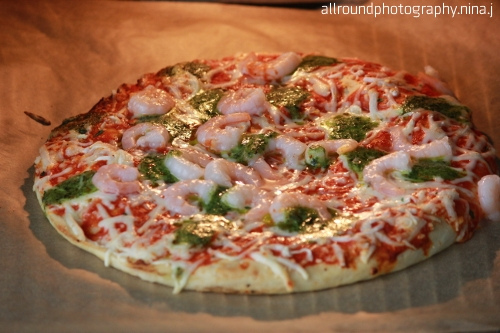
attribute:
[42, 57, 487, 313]
pizza — delicious